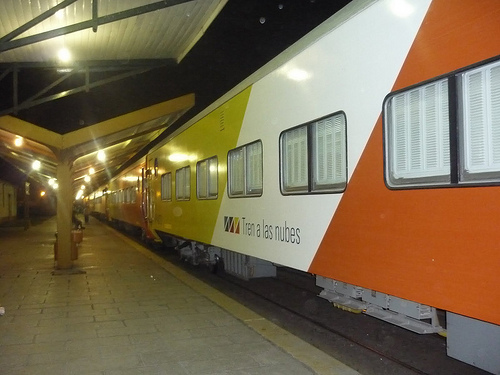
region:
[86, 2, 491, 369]
a train at a train station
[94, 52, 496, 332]
an orange white yellow train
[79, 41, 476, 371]
a passenger train parked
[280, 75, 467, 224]
windows on a train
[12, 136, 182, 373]
a sidewalk next to train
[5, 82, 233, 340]
a sidewalk with awning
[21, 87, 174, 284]
an awning with lights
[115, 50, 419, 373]
a train at night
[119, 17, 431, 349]
a train in the dark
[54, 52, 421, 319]
a train on tracks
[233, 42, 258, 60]
the sky is pitch black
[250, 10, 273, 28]
the moon in the sky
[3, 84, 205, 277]
the awning of the platform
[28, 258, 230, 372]
the platform beside the train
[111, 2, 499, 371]
the train is orange, yellow, and white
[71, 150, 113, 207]
the lights on the awning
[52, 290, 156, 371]
the platform is tiled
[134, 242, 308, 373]
the edge of the platform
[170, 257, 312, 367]
the line at the edge of the platform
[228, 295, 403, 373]
the line is yellow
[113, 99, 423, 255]
large train in multiple colors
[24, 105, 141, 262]
lights on at the train tracks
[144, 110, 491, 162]
many windows on the train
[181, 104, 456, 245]
orange yellow and white stripes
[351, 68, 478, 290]
orange section of the train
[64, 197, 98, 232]
person waiting for the train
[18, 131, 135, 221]
two rows of round lights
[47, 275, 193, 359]
brick side walk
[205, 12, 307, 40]
dark sky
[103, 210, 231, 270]
wheels on the train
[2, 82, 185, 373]
a train station at night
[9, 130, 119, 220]
the lights are hanging from the ceiling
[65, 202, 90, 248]
people are waiting for the train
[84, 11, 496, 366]
the train is in the station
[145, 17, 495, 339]
the sleeper car is yellow, white, and orange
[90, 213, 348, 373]
a yellow caution line on the edge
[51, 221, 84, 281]
benches are under cover at the station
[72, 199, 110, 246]
a person is walking to a train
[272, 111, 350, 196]
the windows of the car have shutters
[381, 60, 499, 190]
the shutters are white on the windows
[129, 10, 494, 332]
a yellow white and orange passenger train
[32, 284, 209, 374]
yellow and beige brick walkway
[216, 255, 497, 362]
the gray undercarriage of the train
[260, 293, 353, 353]
gray concrete under the train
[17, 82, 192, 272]
a large white eave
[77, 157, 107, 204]
a series of lights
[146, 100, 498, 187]
windows along the side of the train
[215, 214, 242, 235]
a colorful logo on the side of the train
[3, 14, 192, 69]
a large white overhang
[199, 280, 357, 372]
a concrete curb